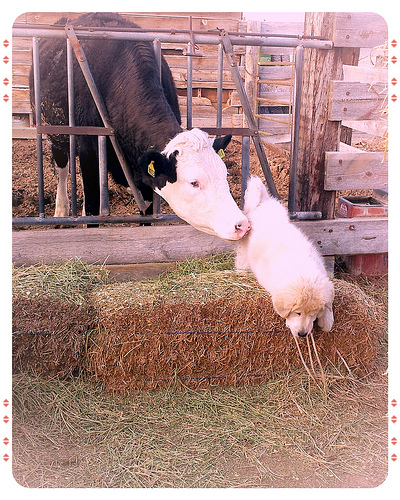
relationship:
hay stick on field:
[278, 326, 356, 405] [0, 261, 392, 485]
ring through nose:
[235, 222, 253, 234] [225, 206, 254, 243]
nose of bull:
[225, 206, 254, 243] [29, 13, 250, 242]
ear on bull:
[212, 133, 232, 151] [29, 13, 250, 242]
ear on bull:
[136, 150, 167, 176] [29, 13, 250, 242]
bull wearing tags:
[29, 13, 250, 242] [216, 147, 224, 158]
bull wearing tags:
[29, 13, 250, 242] [146, 160, 156, 178]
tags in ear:
[216, 147, 224, 158] [212, 133, 232, 151]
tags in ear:
[146, 160, 156, 178] [136, 148, 166, 177]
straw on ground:
[14, 374, 388, 487] [14, 376, 384, 487]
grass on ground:
[13, 375, 387, 486] [14, 376, 384, 487]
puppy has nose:
[232, 167, 335, 360] [298, 327, 306, 337]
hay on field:
[13, 266, 394, 487] [12, 367, 393, 489]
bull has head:
[29, 13, 250, 242] [139, 128, 251, 243]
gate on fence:
[13, 25, 330, 221] [14, 20, 393, 274]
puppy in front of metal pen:
[232, 167, 335, 360] [6, 21, 331, 228]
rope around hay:
[135, 328, 329, 339] [276, 373, 322, 408]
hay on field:
[13, 266, 394, 487] [32, 268, 396, 496]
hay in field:
[13, 266, 394, 487] [17, 111, 398, 432]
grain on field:
[28, 377, 365, 457] [19, 19, 386, 476]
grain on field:
[7, 259, 385, 488] [19, 19, 386, 476]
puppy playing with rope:
[232, 167, 335, 360] [283, 339, 350, 397]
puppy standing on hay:
[232, 167, 335, 360] [13, 266, 394, 487]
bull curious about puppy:
[29, 13, 250, 242] [234, 173, 335, 338]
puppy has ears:
[232, 167, 335, 360] [272, 276, 302, 327]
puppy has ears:
[232, 167, 335, 360] [317, 271, 339, 339]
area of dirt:
[225, 449, 398, 486] [263, 451, 351, 480]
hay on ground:
[13, 266, 394, 487] [20, 269, 384, 486]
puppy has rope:
[232, 167, 335, 360] [294, 331, 342, 433]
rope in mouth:
[294, 331, 342, 433] [287, 320, 312, 337]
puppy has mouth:
[232, 167, 335, 360] [287, 320, 312, 337]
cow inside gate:
[25, 9, 251, 245] [10, 9, 388, 301]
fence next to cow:
[294, 25, 383, 214] [130, 107, 250, 243]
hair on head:
[161, 126, 214, 159] [146, 121, 251, 244]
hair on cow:
[161, 126, 214, 159] [25, 9, 251, 245]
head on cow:
[146, 121, 251, 244] [25, 9, 251, 245]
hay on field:
[13, 266, 394, 487] [19, 19, 386, 476]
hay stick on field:
[278, 326, 356, 405] [19, 19, 386, 476]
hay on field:
[13, 266, 394, 487] [14, 390, 381, 478]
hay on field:
[13, 266, 381, 386] [19, 19, 386, 476]